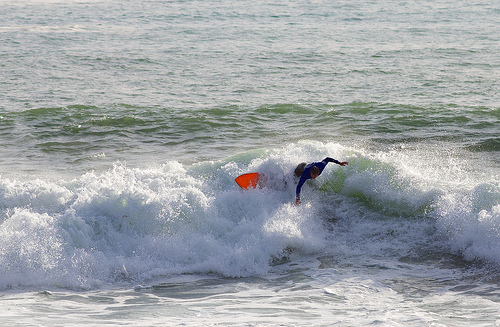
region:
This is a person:
[274, 130, 358, 207]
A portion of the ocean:
[17, 173, 75, 216]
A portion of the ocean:
[75, 165, 167, 228]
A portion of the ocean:
[17, 233, 112, 299]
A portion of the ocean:
[192, 212, 315, 284]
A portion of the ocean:
[326, 213, 444, 299]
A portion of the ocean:
[426, 158, 493, 246]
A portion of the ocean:
[403, 75, 497, 177]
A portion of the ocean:
[143, 60, 230, 139]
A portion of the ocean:
[317, 3, 454, 135]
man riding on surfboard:
[288, 156, 348, 201]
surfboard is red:
[228, 155, 291, 198]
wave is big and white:
[3, 134, 498, 274]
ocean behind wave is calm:
[2, 3, 496, 319]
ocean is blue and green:
[3, 6, 491, 308]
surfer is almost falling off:
[230, 150, 351, 215]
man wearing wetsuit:
[289, 145, 354, 208]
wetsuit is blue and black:
[290, 153, 345, 200]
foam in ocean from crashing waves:
[0, 272, 499, 324]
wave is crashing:
[3, 134, 496, 279]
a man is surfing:
[133, 108, 398, 286]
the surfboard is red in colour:
[201, 57, 276, 224]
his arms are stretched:
[288, 121, 368, 220]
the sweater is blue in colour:
[292, 157, 360, 192]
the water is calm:
[108, 41, 357, 113]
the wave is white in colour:
[36, 149, 289, 280]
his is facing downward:
[248, 145, 375, 214]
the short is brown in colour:
[288, 153, 305, 172]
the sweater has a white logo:
[309, 152, 327, 166]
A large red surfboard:
[232, 172, 255, 189]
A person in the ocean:
[291, 157, 348, 205]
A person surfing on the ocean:
[295, 156, 347, 205]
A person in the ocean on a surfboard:
[234, 156, 349, 204]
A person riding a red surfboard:
[233, 157, 350, 206]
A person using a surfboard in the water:
[235, 157, 347, 205]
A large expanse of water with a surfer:
[0, 0, 499, 324]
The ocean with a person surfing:
[0, 2, 498, 325]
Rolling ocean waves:
[2, 137, 499, 285]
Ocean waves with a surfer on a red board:
[2, 137, 498, 290]